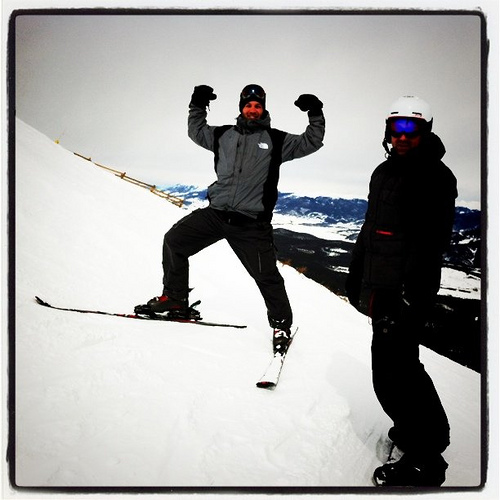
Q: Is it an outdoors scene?
A: Yes, it is outdoors.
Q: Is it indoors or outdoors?
A: It is outdoors.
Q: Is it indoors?
A: No, it is outdoors.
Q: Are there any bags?
A: No, there are no bags.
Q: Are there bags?
A: No, there are no bags.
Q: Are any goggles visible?
A: Yes, there are goggles.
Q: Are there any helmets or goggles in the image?
A: Yes, there are goggles.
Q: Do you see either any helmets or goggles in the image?
A: Yes, there are goggles.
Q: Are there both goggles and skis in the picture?
A: Yes, there are both goggles and skis.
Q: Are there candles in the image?
A: No, there are no candles.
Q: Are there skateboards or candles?
A: No, there are no candles or skateboards.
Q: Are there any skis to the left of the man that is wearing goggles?
A: Yes, there is a ski to the left of the man.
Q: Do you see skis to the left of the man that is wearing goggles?
A: Yes, there is a ski to the left of the man.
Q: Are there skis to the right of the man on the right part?
A: No, the ski is to the left of the man.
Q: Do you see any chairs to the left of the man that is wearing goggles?
A: No, there is a ski to the left of the man.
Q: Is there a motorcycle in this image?
A: No, there are no motorcycles.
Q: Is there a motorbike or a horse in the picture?
A: No, there are no motorcycles or horses.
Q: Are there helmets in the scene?
A: Yes, there is a helmet.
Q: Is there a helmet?
A: Yes, there is a helmet.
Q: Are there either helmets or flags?
A: Yes, there is a helmet.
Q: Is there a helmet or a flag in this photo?
A: Yes, there is a helmet.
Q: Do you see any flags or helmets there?
A: Yes, there is a helmet.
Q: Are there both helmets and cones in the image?
A: No, there is a helmet but no cones.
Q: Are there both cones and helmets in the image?
A: No, there is a helmet but no cones.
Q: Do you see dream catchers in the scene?
A: No, there are no dream catchers.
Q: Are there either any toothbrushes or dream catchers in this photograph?
A: No, there are no dream catchers or toothbrushes.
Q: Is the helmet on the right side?
A: Yes, the helmet is on the right of the image.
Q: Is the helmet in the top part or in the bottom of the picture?
A: The helmet is in the top of the image.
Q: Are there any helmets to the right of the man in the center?
A: Yes, there is a helmet to the right of the man.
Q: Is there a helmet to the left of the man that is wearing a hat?
A: No, the helmet is to the right of the man.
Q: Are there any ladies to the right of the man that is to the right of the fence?
A: No, there is a helmet to the right of the man.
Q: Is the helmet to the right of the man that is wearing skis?
A: Yes, the helmet is to the right of the man.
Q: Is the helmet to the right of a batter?
A: No, the helmet is to the right of the man.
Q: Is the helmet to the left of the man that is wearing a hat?
A: No, the helmet is to the right of the man.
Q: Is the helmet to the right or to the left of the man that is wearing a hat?
A: The helmet is to the right of the man.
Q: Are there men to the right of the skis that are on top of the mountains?
A: Yes, there is a man to the right of the skis.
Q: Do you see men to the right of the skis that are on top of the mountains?
A: Yes, there is a man to the right of the skis.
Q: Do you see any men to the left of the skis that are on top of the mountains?
A: No, the man is to the right of the skis.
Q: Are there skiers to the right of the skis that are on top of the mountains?
A: No, there is a man to the right of the skis.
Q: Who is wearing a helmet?
A: The man is wearing a helmet.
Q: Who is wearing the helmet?
A: The man is wearing a helmet.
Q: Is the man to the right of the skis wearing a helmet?
A: Yes, the man is wearing a helmet.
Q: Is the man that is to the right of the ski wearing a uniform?
A: No, the man is wearing a helmet.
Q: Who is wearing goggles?
A: The man is wearing goggles.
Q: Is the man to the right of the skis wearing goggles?
A: Yes, the man is wearing goggles.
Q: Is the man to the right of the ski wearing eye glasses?
A: No, the man is wearing goggles.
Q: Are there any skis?
A: Yes, there are skis.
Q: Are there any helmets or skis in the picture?
A: Yes, there are skis.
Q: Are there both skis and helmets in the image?
A: Yes, there are both skis and a helmet.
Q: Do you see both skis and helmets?
A: Yes, there are both skis and a helmet.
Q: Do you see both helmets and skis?
A: Yes, there are both skis and a helmet.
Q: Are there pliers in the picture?
A: No, there are no pliers.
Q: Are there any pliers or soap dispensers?
A: No, there are no pliers or soap dispensers.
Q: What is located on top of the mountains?
A: The skis are on top of the mountains.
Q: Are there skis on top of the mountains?
A: Yes, there are skis on top of the mountains.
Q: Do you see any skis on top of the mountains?
A: Yes, there are skis on top of the mountains.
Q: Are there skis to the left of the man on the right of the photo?
A: Yes, there are skis to the left of the man.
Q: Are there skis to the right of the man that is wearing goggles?
A: No, the skis are to the left of the man.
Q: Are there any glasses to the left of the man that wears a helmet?
A: No, there are skis to the left of the man.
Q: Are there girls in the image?
A: No, there are no girls.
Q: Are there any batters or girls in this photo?
A: No, there are no girls or batters.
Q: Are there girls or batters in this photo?
A: No, there are no girls or batters.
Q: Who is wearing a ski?
A: The man is wearing a ski.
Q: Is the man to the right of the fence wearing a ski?
A: Yes, the man is wearing a ski.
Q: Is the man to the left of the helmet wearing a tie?
A: No, the man is wearing a ski.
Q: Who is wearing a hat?
A: The man is wearing a hat.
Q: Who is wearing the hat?
A: The man is wearing a hat.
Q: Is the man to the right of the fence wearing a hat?
A: Yes, the man is wearing a hat.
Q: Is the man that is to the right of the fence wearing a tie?
A: No, the man is wearing a hat.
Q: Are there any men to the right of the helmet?
A: No, the man is to the left of the helmet.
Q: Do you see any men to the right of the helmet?
A: No, the man is to the left of the helmet.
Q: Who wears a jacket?
A: The man wears a jacket.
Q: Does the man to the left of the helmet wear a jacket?
A: Yes, the man wears a jacket.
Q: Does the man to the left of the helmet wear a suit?
A: No, the man wears a jacket.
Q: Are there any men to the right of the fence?
A: Yes, there is a man to the right of the fence.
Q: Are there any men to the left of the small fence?
A: No, the man is to the right of the fence.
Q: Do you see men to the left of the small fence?
A: No, the man is to the right of the fence.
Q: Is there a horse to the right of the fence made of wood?
A: No, there is a man to the right of the fence.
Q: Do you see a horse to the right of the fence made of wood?
A: No, there is a man to the right of the fence.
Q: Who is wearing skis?
A: The man is wearing skis.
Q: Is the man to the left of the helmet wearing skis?
A: Yes, the man is wearing skis.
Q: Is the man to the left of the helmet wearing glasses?
A: No, the man is wearing skis.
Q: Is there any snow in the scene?
A: Yes, there is snow.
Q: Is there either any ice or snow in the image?
A: Yes, there is snow.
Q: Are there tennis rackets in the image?
A: No, there are no tennis rackets.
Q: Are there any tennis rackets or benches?
A: No, there are no tennis rackets or benches.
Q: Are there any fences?
A: Yes, there is a fence.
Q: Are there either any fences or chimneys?
A: Yes, there is a fence.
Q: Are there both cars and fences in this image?
A: No, there is a fence but no cars.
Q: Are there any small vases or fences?
A: Yes, there is a small fence.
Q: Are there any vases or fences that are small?
A: Yes, the fence is small.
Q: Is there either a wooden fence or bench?
A: Yes, there is a wood fence.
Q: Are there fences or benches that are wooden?
A: Yes, the fence is wooden.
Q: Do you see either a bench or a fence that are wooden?
A: Yes, the fence is wooden.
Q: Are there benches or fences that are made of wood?
A: Yes, the fence is made of wood.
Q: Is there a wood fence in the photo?
A: Yes, there is a wood fence.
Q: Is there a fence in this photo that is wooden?
A: Yes, there is a fence that is wooden.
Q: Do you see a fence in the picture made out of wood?
A: Yes, there is a fence that is made of wood.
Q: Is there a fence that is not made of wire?
A: Yes, there is a fence that is made of wood.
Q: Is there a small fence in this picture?
A: Yes, there is a small fence.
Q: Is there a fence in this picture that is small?
A: Yes, there is a fence that is small.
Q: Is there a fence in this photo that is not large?
A: Yes, there is a small fence.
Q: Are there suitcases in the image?
A: No, there are no suitcases.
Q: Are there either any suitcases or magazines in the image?
A: No, there are no suitcases or magazines.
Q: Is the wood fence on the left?
A: Yes, the fence is on the left of the image.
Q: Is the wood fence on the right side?
A: No, the fence is on the left of the image.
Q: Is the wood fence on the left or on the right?
A: The fence is on the left of the image.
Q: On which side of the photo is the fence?
A: The fence is on the left of the image.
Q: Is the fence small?
A: Yes, the fence is small.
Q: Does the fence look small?
A: Yes, the fence is small.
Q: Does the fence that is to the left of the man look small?
A: Yes, the fence is small.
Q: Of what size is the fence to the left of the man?
A: The fence is small.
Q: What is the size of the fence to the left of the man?
A: The fence is small.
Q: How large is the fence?
A: The fence is small.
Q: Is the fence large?
A: No, the fence is small.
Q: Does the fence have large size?
A: No, the fence is small.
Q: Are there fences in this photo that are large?
A: No, there is a fence but it is small.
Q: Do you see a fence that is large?
A: No, there is a fence but it is small.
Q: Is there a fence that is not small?
A: No, there is a fence but it is small.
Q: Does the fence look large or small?
A: The fence is small.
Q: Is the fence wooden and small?
A: Yes, the fence is wooden and small.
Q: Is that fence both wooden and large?
A: No, the fence is wooden but small.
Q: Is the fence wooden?
A: Yes, the fence is wooden.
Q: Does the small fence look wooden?
A: Yes, the fence is wooden.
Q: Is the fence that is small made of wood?
A: Yes, the fence is made of wood.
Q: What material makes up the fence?
A: The fence is made of wood.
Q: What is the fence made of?
A: The fence is made of wood.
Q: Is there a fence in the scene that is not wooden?
A: No, there is a fence but it is wooden.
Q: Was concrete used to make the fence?
A: No, the fence is made of wood.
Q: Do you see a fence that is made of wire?
A: No, there is a fence but it is made of wood.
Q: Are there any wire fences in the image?
A: No, there is a fence but it is made of wood.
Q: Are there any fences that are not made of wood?
A: No, there is a fence but it is made of wood.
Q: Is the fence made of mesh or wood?
A: The fence is made of wood.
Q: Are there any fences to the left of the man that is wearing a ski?
A: Yes, there is a fence to the left of the man.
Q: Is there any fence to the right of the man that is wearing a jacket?
A: No, the fence is to the left of the man.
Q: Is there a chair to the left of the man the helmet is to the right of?
A: No, there is a fence to the left of the man.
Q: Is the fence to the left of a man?
A: Yes, the fence is to the left of a man.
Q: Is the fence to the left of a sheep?
A: No, the fence is to the left of a man.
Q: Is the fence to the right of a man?
A: No, the fence is to the left of a man.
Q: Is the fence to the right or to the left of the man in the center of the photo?
A: The fence is to the left of the man.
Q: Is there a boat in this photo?
A: No, there are no boats.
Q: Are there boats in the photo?
A: No, there are no boats.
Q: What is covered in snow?
A: The mountains are covered in snow.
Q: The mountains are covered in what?
A: The mountains are covered in snow.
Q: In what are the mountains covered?
A: The mountains are covered in snow.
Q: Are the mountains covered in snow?
A: Yes, the mountains are covered in snow.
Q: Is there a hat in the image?
A: Yes, there is a hat.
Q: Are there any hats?
A: Yes, there is a hat.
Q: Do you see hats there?
A: Yes, there is a hat.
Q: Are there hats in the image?
A: Yes, there is a hat.